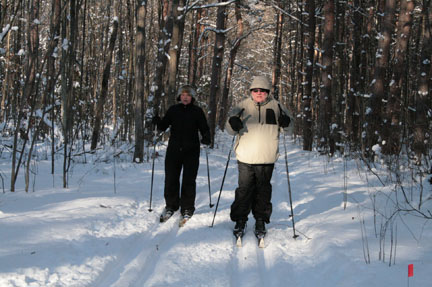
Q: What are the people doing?
A: Skiing.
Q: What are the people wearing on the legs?
A: Black pants.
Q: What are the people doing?
A: Skiing.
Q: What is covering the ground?
A: Snow.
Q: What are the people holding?
A: Poles.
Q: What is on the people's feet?
A: Skis.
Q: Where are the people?
A: Among trees.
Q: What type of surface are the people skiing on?
A: Flat surface.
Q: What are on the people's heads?
A: Hats.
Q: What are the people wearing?
A: Jackets.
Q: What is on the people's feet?
A: Skis.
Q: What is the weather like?
A: Cold and clear.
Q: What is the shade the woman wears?
A: All black.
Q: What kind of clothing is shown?
A: Parka.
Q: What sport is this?
A: Skiing.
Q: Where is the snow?
A: On the ground.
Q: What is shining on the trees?
A: Sun.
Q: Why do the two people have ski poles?
A: To propel themselves.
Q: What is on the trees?
A: Snow.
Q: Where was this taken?
A: In a forest.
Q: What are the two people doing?
A: Cross-country skiing.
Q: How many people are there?
A: Two.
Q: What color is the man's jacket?
A: Beige.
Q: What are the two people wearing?
A: Cold weather clothes.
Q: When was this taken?
A: During the day.